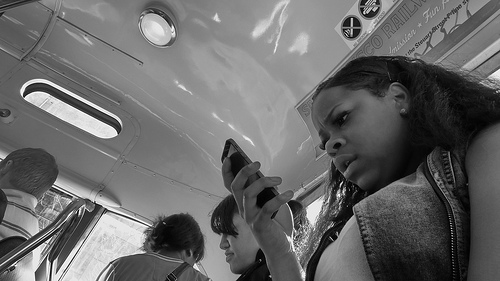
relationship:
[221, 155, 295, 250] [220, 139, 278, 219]
hand holding phone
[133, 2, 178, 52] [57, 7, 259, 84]
light on ceiling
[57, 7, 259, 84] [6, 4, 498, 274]
ceiling on bus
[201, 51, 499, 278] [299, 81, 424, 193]
girl has face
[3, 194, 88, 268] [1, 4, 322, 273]
safety bar on bus